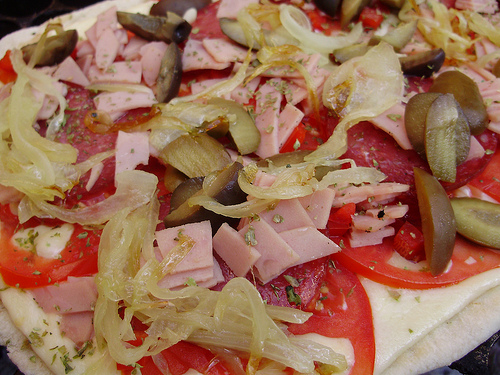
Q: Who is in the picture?
A: Nobody.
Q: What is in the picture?
A: Food.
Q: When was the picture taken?
A: After the food was made.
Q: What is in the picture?
A: Meat, olives, onion, tomatoes and cheese.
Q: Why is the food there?
A: To be eaten.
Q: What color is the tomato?
A: Red.